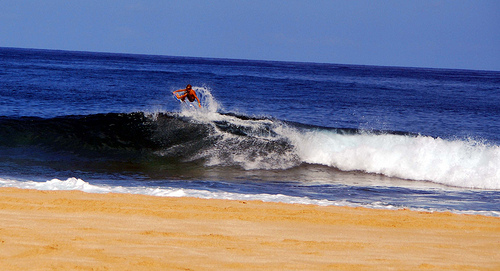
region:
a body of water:
[55, 43, 375, 158]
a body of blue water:
[101, 58, 440, 218]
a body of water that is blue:
[159, 58, 443, 215]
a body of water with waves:
[78, 38, 397, 152]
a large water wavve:
[110, 47, 442, 221]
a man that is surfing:
[129, 41, 321, 188]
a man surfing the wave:
[137, 68, 304, 190]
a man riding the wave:
[165, 64, 300, 216]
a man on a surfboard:
[114, 52, 284, 180]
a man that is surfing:
[107, 41, 439, 269]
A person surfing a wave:
[170, 81, 222, 128]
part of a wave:
[374, 141, 379, 157]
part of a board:
[199, 93, 215, 118]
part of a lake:
[331, 130, 338, 155]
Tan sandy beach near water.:
[369, 231, 436, 266]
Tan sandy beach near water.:
[200, 213, 245, 263]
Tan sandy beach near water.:
[62, 201, 98, 243]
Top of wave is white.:
[417, 147, 452, 179]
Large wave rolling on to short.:
[115, 120, 240, 168]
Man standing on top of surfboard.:
[169, 86, 197, 112]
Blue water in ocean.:
[378, 92, 429, 131]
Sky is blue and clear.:
[78, 29, 143, 46]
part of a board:
[232, 103, 241, 113]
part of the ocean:
[345, 100, 357, 132]